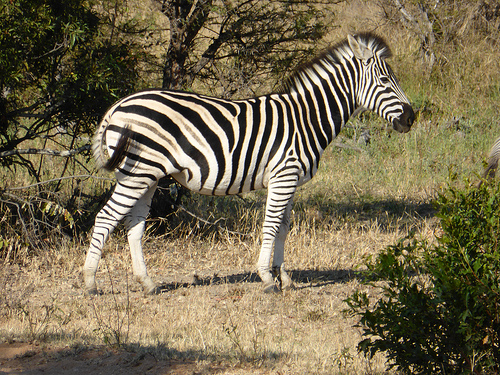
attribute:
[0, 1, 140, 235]
tree — present, green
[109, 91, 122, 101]
leaf — green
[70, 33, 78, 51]
leaf — green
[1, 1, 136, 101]
leaves — green, small, dark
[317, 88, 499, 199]
grass — green, present, dry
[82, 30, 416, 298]
zebra — white, black, present, standing, looking, full-grown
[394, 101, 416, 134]
mouth — black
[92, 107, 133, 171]
tail — curled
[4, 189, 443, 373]
ground — flat, brown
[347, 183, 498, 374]
bush — present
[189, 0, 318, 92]
branch — dark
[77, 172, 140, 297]
leg — rear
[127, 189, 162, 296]
leg — rear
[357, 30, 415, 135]
head — slightly turned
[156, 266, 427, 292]
shadow — thin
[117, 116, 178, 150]
stripe — grey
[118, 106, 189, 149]
stripe — white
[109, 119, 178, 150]
stripe — black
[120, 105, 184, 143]
stripe — black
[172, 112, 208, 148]
stripe — faded, grey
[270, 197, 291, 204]
stripe — black, narrow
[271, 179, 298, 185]
stripe — black, narrow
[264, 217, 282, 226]
stripe — black, narrow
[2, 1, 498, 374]
field — dry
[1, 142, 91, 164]
branch — bare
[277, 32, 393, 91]
mane — short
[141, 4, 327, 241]
tree — present